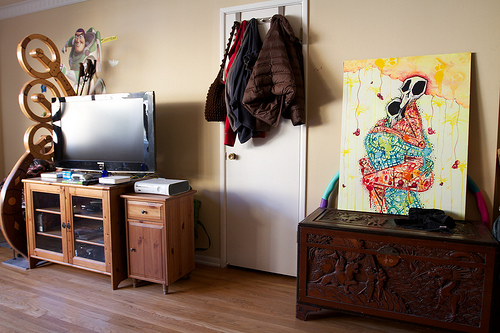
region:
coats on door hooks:
[222, 24, 311, 124]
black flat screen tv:
[62, 91, 157, 171]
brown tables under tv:
[35, 165, 186, 298]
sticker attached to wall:
[63, 19, 111, 77]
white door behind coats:
[222, 16, 300, 268]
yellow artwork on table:
[342, 74, 464, 216]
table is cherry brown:
[288, 199, 498, 326]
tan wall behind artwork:
[368, 8, 454, 33]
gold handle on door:
[222, 139, 254, 166]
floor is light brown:
[185, 264, 301, 321]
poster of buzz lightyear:
[58, 26, 105, 93]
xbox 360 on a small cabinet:
[133, 177, 190, 196]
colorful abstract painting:
[338, 50, 473, 220]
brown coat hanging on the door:
[241, 13, 304, 131]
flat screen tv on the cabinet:
[50, 88, 157, 172]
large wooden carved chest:
[296, 206, 499, 331]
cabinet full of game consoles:
[19, 173, 149, 290]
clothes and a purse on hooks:
[204, 13, 306, 147]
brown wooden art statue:
[0, 32, 77, 271]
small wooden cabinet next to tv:
[118, 188, 196, 295]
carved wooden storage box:
[291, 202, 499, 328]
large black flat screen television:
[47, 88, 159, 180]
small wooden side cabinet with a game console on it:
[121, 172, 201, 298]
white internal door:
[218, 3, 311, 286]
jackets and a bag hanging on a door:
[196, 4, 319, 149]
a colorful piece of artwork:
[333, 50, 474, 222]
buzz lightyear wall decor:
[56, 25, 121, 90]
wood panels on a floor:
[1, 244, 408, 331]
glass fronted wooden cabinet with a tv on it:
[20, 78, 159, 288]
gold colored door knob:
[226, 150, 237, 163]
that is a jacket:
[247, 26, 291, 134]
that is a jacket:
[206, 20, 256, 131]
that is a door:
[221, 154, 303, 265]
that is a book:
[135, 170, 180, 190]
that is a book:
[97, 170, 132, 185]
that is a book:
[38, 168, 63, 178]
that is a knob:
[229, 149, 239, 171]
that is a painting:
[341, 54, 470, 210]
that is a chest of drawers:
[77, 188, 112, 276]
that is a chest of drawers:
[26, 186, 63, 262]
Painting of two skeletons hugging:
[332, 46, 472, 219]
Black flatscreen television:
[47, 90, 157, 175]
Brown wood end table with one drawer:
[120, 190, 197, 295]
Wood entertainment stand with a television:
[20, 91, 160, 290]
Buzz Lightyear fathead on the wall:
[55, 26, 118, 96]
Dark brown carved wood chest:
[293, 203, 495, 332]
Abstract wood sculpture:
[0, 30, 83, 272]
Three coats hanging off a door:
[219, 13, 309, 148]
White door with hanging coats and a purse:
[200, 0, 311, 277]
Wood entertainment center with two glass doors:
[22, 171, 154, 289]